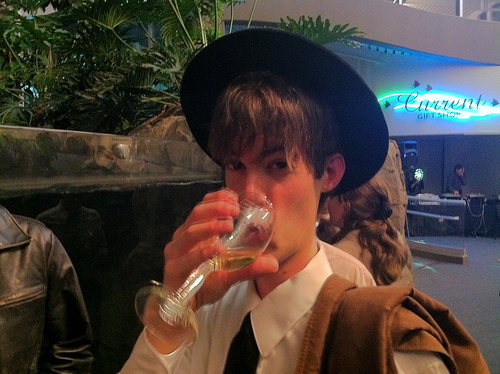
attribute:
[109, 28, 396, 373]
person — drinking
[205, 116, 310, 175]
bangs — black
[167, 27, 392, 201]
hat — dark, black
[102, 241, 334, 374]
shirt — long sleeve, white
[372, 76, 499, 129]
sign — bright, neon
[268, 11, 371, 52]
plant — green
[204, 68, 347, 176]
hair — brown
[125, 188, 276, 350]
glass — wine glass, clear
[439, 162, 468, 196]
man — chatting, standing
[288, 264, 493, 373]
jacket — light brown, black, brown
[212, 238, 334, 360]
collar — white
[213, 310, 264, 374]
tie — dark colored, black